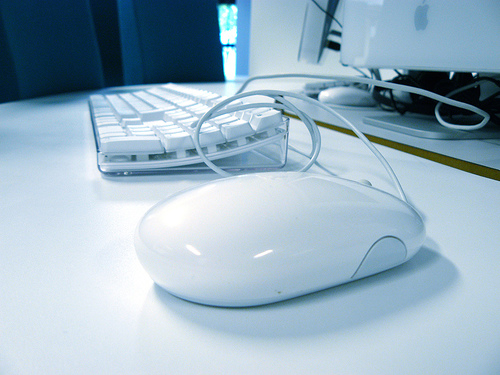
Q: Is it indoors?
A: Yes, it is indoors.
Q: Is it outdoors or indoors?
A: It is indoors.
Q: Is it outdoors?
A: No, it is indoors.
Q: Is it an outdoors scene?
A: No, it is indoors.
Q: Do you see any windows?
A: Yes, there is a window.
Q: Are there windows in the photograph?
A: Yes, there is a window.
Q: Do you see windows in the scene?
A: Yes, there is a window.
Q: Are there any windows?
A: Yes, there is a window.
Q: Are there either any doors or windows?
A: Yes, there is a window.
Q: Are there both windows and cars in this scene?
A: No, there is a window but no cars.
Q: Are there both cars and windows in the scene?
A: No, there is a window but no cars.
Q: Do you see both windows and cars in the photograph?
A: No, there is a window but no cars.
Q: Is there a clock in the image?
A: No, there are no clocks.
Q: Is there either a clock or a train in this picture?
A: No, there are no clocks or trains.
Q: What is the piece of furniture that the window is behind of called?
A: The piece of furniture is a table.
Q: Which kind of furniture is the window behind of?
A: The window is behind the table.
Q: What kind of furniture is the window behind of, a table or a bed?
A: The window is behind a table.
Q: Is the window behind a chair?
A: No, the window is behind the table.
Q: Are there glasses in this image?
A: No, there are no glasses.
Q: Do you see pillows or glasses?
A: No, there are no glasses or pillows.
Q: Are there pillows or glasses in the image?
A: No, there are no glasses or pillows.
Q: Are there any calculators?
A: No, there are no calculators.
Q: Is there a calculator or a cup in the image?
A: No, there are no calculators or cups.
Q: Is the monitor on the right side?
A: Yes, the monitor is on the right of the image.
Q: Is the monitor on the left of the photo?
A: No, the monitor is on the right of the image.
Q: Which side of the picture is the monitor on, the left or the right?
A: The monitor is on the right of the image.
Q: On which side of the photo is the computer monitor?
A: The monitor is on the right of the image.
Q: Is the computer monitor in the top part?
A: Yes, the monitor is in the top of the image.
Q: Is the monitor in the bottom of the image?
A: No, the monitor is in the top of the image.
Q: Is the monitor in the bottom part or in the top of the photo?
A: The monitor is in the top of the image.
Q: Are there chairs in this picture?
A: No, there are no chairs.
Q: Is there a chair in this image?
A: No, there are no chairs.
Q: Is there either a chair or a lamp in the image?
A: No, there are no chairs or lamps.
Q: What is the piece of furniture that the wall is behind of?
A: The piece of furniture is a table.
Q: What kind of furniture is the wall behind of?
A: The wall is behind the table.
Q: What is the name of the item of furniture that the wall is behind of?
A: The piece of furniture is a table.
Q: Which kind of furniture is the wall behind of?
A: The wall is behind the table.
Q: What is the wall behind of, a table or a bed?
A: The wall is behind a table.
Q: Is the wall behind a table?
A: Yes, the wall is behind a table.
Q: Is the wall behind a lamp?
A: No, the wall is behind a table.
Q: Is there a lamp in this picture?
A: No, there are no lamps.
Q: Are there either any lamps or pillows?
A: No, there are no lamps or pillows.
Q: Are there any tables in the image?
A: Yes, there is a table.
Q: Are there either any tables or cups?
A: Yes, there is a table.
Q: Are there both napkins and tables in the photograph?
A: No, there is a table but no napkins.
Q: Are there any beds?
A: No, there are no beds.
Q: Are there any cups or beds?
A: No, there are no beds or cups.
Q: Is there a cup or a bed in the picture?
A: No, there are no beds or cups.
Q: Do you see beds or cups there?
A: No, there are no beds or cups.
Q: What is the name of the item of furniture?
A: The piece of furniture is a table.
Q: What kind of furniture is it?
A: The piece of furniture is a table.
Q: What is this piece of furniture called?
A: This is a table.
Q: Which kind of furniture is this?
A: This is a table.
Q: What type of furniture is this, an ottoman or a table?
A: This is a table.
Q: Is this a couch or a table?
A: This is a table.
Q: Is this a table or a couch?
A: This is a table.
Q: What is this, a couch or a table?
A: This is a table.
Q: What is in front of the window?
A: The table is in front of the window.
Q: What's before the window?
A: The table is in front of the window.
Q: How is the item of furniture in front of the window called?
A: The piece of furniture is a table.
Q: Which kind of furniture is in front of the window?
A: The piece of furniture is a table.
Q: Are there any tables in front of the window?
A: Yes, there is a table in front of the window.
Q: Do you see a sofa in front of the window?
A: No, there is a table in front of the window.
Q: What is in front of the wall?
A: The table is in front of the wall.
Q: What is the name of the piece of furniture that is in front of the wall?
A: The piece of furniture is a table.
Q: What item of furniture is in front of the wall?
A: The piece of furniture is a table.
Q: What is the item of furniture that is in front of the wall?
A: The piece of furniture is a table.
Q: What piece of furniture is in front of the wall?
A: The piece of furniture is a table.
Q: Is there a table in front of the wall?
A: Yes, there is a table in front of the wall.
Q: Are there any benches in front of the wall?
A: No, there is a table in front of the wall.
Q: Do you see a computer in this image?
A: Yes, there is a computer.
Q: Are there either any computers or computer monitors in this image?
A: Yes, there is a computer.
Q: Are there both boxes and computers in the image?
A: No, there is a computer but no boxes.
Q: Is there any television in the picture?
A: No, there are no televisions.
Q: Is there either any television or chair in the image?
A: No, there are no televisions or chairs.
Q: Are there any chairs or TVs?
A: No, there are no TVs or chairs.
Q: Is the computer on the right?
A: Yes, the computer is on the right of the image.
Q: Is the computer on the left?
A: No, the computer is on the right of the image.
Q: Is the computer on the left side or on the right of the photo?
A: The computer is on the right of the image.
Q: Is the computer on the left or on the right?
A: The computer is on the right of the image.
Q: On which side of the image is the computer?
A: The computer is on the right of the image.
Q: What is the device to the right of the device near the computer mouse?
A: The device is a computer.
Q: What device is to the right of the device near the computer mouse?
A: The device is a computer.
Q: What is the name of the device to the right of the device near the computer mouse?
A: The device is a computer.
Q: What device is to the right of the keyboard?
A: The device is a computer.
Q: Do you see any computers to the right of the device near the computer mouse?
A: Yes, there is a computer to the right of the keyboard.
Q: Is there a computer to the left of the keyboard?
A: No, the computer is to the right of the keyboard.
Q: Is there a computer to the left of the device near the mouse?
A: No, the computer is to the right of the keyboard.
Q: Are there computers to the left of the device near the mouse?
A: No, the computer is to the right of the keyboard.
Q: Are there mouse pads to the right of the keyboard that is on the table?
A: No, there is a computer to the right of the keyboard.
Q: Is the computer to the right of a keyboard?
A: Yes, the computer is to the right of a keyboard.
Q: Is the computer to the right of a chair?
A: No, the computer is to the right of a keyboard.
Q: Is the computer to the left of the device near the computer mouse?
A: No, the computer is to the right of the keyboard.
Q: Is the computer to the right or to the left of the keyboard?
A: The computer is to the right of the keyboard.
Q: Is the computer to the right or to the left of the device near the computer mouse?
A: The computer is to the right of the keyboard.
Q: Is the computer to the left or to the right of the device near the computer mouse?
A: The computer is to the right of the keyboard.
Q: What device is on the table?
A: The device is a computer.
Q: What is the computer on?
A: The computer is on the table.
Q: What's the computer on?
A: The computer is on the table.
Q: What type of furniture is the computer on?
A: The computer is on the table.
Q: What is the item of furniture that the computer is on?
A: The piece of furniture is a table.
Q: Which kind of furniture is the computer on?
A: The computer is on the table.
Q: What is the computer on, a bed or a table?
A: The computer is on a table.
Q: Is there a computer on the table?
A: Yes, there is a computer on the table.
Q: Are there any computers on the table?
A: Yes, there is a computer on the table.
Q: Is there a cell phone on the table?
A: No, there is a computer on the table.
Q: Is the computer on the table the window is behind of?
A: Yes, the computer is on the table.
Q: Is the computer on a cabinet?
A: No, the computer is on the table.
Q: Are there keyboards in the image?
A: Yes, there is a keyboard.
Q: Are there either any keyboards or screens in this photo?
A: Yes, there is a keyboard.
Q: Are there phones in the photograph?
A: No, there are no phones.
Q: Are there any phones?
A: No, there are no phones.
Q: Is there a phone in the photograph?
A: No, there are no phones.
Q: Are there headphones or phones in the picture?
A: No, there are no phones or headphones.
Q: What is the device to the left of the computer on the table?
A: The device is a keyboard.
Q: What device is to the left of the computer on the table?
A: The device is a keyboard.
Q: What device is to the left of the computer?
A: The device is a keyboard.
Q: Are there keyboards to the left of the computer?
A: Yes, there is a keyboard to the left of the computer.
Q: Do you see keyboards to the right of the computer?
A: No, the keyboard is to the left of the computer.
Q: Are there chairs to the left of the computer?
A: No, there is a keyboard to the left of the computer.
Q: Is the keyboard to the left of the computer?
A: Yes, the keyboard is to the left of the computer.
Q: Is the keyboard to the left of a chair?
A: No, the keyboard is to the left of the computer.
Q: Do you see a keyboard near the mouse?
A: Yes, there is a keyboard near the mouse.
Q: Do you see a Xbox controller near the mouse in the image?
A: No, there is a keyboard near the mouse.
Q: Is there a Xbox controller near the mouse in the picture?
A: No, there is a keyboard near the mouse.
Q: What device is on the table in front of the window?
A: The device is a keyboard.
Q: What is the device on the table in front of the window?
A: The device is a keyboard.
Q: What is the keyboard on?
A: The keyboard is on the table.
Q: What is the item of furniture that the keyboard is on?
A: The piece of furniture is a table.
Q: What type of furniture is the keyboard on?
A: The keyboard is on the table.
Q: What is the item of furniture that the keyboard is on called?
A: The piece of furniture is a table.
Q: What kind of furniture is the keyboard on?
A: The keyboard is on the table.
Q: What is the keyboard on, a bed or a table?
A: The keyboard is on a table.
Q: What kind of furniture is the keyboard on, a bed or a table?
A: The keyboard is on a table.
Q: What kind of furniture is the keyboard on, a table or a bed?
A: The keyboard is on a table.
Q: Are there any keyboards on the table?
A: Yes, there is a keyboard on the table.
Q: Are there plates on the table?
A: No, there is a keyboard on the table.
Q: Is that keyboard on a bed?
A: No, the keyboard is on the table.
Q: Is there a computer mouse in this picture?
A: Yes, there is a computer mouse.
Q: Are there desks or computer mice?
A: Yes, there is a computer mouse.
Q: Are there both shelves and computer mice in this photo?
A: No, there is a computer mouse but no shelves.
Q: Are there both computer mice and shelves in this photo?
A: No, there is a computer mouse but no shelves.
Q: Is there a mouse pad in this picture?
A: No, there are no mouse pads.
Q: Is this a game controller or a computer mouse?
A: This is a computer mouse.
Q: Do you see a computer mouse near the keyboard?
A: Yes, there is a computer mouse near the keyboard.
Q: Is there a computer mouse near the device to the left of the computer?
A: Yes, there is a computer mouse near the keyboard.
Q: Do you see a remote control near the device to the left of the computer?
A: No, there is a computer mouse near the keyboard.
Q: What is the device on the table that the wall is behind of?
A: The device is a computer mouse.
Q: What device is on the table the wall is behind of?
A: The device is a computer mouse.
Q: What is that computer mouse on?
A: The computer mouse is on the table.